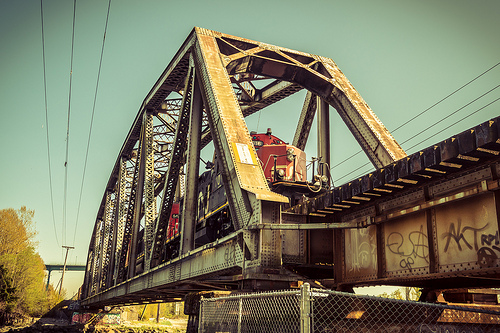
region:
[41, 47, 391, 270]
a tall bridge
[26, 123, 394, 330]
the background color is tarn yellow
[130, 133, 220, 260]
the walls of th bridge are metallic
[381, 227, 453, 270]
words are scrubbed on the bridge side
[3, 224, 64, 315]
the trees are gren in color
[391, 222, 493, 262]
words are written in black color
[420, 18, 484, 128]
the sky is claera dull blue in color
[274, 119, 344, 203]
the train head is red in color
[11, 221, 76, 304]
the trees re beside the road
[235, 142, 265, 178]
the paper is white in color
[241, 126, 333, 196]
Train front crossing a bridge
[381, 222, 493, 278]
Graffiti on an old bridge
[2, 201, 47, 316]
Tall tree on the side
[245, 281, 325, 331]
Metallic wire fence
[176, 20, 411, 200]
Metal old bridge's crossing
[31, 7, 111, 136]
Wire hanging in the air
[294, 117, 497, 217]
High railroad track crossing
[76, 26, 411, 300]
Old train crossing bridge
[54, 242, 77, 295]
Tall electrical post standing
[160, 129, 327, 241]
Red train crossing a bridge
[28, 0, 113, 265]
some overhanging power cables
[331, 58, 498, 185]
some overhanging power cables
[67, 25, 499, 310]
A large metal bridge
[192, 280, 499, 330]
a chain link fence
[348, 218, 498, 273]
some graffiti on a bridge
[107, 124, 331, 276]
A large red and blue train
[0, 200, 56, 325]
A group of trees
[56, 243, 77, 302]
a large wooden pole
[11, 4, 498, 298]
a clear blue sky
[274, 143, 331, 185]
some headlights on a train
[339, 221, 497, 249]
The graffiti on the bridge.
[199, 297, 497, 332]
The chain linked fence below the bridge.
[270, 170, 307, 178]
The front headlights of the train.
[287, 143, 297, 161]
The center headlights of the train.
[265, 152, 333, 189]
The poles in the front of the train.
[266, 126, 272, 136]
The red light on the train's roof.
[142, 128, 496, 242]
The tracks the train is driving on.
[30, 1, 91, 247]
The wires in the air attached to the light pole.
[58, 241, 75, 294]
The light pole the wires are attached to.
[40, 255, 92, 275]
The overpass in the background.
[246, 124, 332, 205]
part of red train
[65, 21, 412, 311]
bridge over train tracks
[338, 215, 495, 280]
graffiti on train tresle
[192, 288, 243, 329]
part of chain link fence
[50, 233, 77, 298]
telephone pole with wires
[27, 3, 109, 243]
electric wires with blue sky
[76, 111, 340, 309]
train on train tracks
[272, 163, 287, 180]
front light on train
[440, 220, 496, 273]
graffiti on train tresle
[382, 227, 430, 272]
graffiti on train tresle